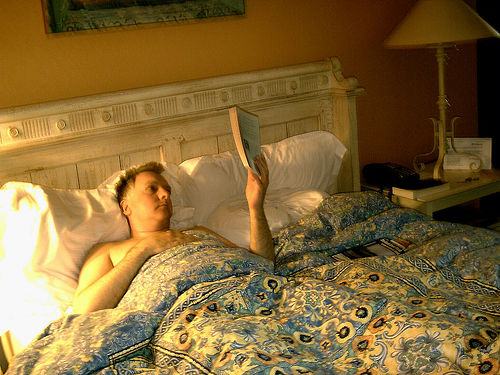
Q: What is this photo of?
A: A room.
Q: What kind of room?
A: A bedroom.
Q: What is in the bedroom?
A: A bed.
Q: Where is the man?
A: In the bed.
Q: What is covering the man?
A: A blanket.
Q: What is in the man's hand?
A: A book.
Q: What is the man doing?
A: Reading a book.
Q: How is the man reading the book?
A: Laying down.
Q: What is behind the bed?
A: A wall.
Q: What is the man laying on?
A: A bed.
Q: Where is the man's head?
A: On the pillow.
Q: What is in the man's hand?
A: A book.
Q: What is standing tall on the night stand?
A: A lamp.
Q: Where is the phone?
A: On the nightstand.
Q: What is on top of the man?
A: The bed spread.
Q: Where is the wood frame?
A: Above the man's head.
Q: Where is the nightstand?
A: Next to the bed.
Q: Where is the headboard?
A: Behind the man's head.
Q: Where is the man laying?
A: In bed.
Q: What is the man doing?
A: Reading in bed.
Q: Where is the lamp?
A: On the table.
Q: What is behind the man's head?
A: A white pillow.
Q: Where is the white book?
A: In the man's hand.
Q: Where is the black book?
A: On the end table.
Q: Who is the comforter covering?
A: The man.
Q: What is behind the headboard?
A: A yellow wall.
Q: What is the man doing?
A: Reading.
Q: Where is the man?
A: In bed.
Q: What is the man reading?
A: A book.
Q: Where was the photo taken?
A: In a bedroom.